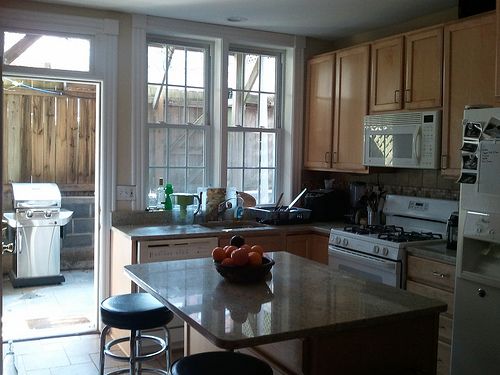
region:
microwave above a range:
[352, 106, 447, 172]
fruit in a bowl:
[245, 250, 262, 265]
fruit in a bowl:
[228, 245, 250, 263]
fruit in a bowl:
[209, 241, 226, 263]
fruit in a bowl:
[250, 242, 265, 255]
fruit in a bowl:
[239, 240, 256, 252]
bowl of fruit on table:
[202, 233, 276, 285]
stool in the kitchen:
[92, 283, 184, 373]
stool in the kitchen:
[164, 343, 282, 373]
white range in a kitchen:
[314, 185, 464, 285]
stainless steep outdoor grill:
[0, 176, 80, 288]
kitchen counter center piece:
[210, 234, 277, 289]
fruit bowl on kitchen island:
[208, 230, 280, 280]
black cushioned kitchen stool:
[86, 286, 176, 373]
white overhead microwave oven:
[363, 110, 441, 166]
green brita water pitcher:
[168, 190, 204, 222]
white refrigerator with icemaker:
[453, 108, 499, 373]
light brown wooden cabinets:
[306, 55, 368, 167]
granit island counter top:
[116, 243, 457, 342]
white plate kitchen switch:
[114, 175, 139, 202]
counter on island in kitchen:
[108, 244, 445, 369]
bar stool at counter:
[84, 290, 166, 373]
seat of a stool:
[168, 350, 281, 374]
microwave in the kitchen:
[361, 110, 438, 170]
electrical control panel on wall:
[113, 179, 140, 205]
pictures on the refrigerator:
[457, 116, 479, 185]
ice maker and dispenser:
[459, 202, 499, 279]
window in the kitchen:
[143, 30, 278, 205]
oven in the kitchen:
[333, 193, 451, 284]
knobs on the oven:
[324, 238, 394, 258]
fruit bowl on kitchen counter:
[205, 235, 275, 282]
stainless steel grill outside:
[1, 178, 81, 290]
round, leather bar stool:
[80, 275, 173, 367]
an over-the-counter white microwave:
[356, 107, 441, 175]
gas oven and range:
[329, 179, 449, 275]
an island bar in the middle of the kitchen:
[125, 252, 451, 349]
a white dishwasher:
[137, 240, 224, 345]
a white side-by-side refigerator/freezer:
[453, 107, 498, 352]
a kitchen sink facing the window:
[199, 187, 298, 232]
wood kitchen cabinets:
[309, 55, 366, 170]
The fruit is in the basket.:
[199, 234, 265, 276]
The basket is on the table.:
[183, 245, 275, 303]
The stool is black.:
[83, 289, 190, 367]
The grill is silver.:
[5, 170, 80, 285]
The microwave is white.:
[358, 108, 450, 180]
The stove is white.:
[325, 188, 454, 288]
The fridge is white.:
[440, 98, 491, 373]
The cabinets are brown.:
[292, 32, 492, 175]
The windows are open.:
[135, 24, 297, 214]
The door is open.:
[0, 80, 110, 342]